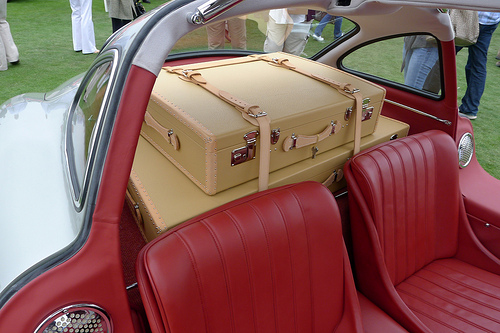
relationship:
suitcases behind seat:
[138, 46, 418, 238] [141, 180, 378, 332]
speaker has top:
[31, 300, 113, 331] [53, 306, 103, 318]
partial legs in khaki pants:
[201, 14, 256, 56] [201, 14, 246, 54]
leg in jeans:
[402, 42, 441, 93] [403, 46, 442, 88]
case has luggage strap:
[133, 50, 388, 196] [162, 66, 270, 191]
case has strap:
[133, 50, 388, 196] [349, 86, 369, 151]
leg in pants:
[459, 14, 494, 118] [463, 7, 498, 112]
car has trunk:
[1, 0, 493, 331] [0, 0, 462, 293]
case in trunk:
[133, 50, 388, 195] [0, 0, 462, 293]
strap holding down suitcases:
[191, 66, 369, 133] [120, 116, 410, 246]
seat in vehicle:
[141, 180, 378, 332] [14, 16, 472, 323]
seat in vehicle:
[141, 180, 378, 332] [28, 28, 485, 327]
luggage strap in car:
[162, 52, 361, 191] [1, 0, 493, 331]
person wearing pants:
[66, 0, 101, 55] [69, 1, 94, 54]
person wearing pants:
[458, 10, 499, 118] [460, 20, 498, 117]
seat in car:
[141, 180, 378, 332] [1, 0, 493, 331]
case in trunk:
[133, 50, 388, 196] [0, 22, 463, 218]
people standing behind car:
[396, 0, 477, 91] [1, 0, 493, 331]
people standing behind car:
[67, 0, 99, 54] [1, 0, 493, 331]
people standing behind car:
[306, 17, 343, 41] [1, 0, 493, 331]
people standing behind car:
[260, 0, 313, 55] [1, 0, 493, 331]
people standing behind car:
[444, 1, 493, 119] [1, 0, 493, 331]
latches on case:
[232, 132, 257, 163] [133, 50, 388, 196]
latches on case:
[360, 102, 373, 121] [133, 50, 388, 196]